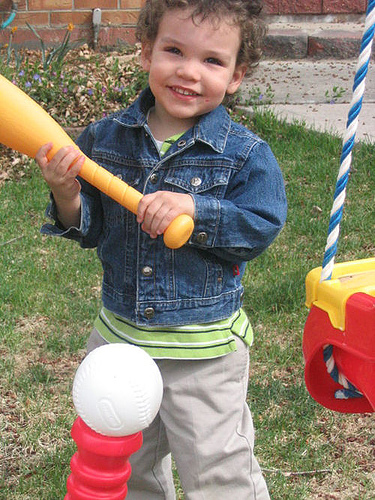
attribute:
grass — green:
[291, 216, 319, 259]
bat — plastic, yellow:
[1, 72, 189, 260]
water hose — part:
[0, 1, 24, 34]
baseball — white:
[65, 334, 165, 436]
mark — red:
[205, 99, 210, 102]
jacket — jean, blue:
[43, 87, 285, 327]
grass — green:
[0, 108, 375, 498]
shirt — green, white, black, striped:
[51, 92, 275, 365]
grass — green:
[280, 126, 325, 197]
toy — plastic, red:
[57, 416, 141, 499]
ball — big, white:
[74, 341, 164, 441]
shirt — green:
[87, 299, 260, 360]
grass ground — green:
[260, 282, 293, 351]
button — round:
[193, 230, 209, 246]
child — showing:
[2, 3, 299, 498]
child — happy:
[35, 0, 286, 335]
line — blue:
[359, 24, 374, 52]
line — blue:
[354, 37, 374, 69]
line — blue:
[350, 55, 371, 91]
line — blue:
[343, 95, 364, 129]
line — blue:
[338, 134, 356, 164]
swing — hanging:
[301, 255, 373, 413]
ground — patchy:
[39, 36, 366, 304]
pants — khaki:
[145, 354, 276, 499]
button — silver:
[186, 173, 205, 188]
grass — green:
[287, 137, 372, 265]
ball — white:
[64, 342, 171, 440]